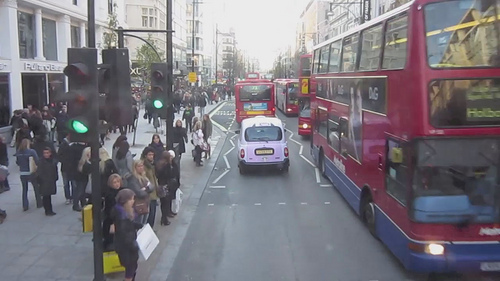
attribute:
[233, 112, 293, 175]
car — painted, pink, white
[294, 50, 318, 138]
bus — double decker, red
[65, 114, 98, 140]
stoplight — green, illuminated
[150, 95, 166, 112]
stoplight — green, illuminated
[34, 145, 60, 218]
pedestrian — waiting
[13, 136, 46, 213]
pedestrian — waiting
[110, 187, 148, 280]
pedestrian — waiting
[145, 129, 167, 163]
pedestrian — waiting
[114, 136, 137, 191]
pedestrian — waiting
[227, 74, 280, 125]
bus — red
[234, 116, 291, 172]
english car — little, white, with tailights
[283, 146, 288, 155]
tail lights — vertical, oblong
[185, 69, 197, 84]
sign — yellow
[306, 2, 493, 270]
bus — red, double decker, new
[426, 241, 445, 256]
headlight — lit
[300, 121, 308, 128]
headlight — lit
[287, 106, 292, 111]
headlight — lit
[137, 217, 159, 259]
bag — white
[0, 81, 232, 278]
sidewalk — busy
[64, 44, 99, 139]
signal — blue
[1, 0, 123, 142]
building — Tall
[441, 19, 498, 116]
buildings — top front window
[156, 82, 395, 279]
street — heavily trafficked, in london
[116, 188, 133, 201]
hair — blonde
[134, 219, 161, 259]
bag — white, shopping bag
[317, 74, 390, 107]
ad — dolce & gabbana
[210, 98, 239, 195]
marking — white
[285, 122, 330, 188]
marking — white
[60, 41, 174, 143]
traffic lights — green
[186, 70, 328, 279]
street —  double deckered,  has markings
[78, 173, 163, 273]
bag — white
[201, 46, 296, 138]
bus — red,  double deckered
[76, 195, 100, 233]
box — yellow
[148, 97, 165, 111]
light — green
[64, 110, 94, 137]
light — green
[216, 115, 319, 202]
markings —  jaggedy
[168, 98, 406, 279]
street — of city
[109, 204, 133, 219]
scarf — lavender